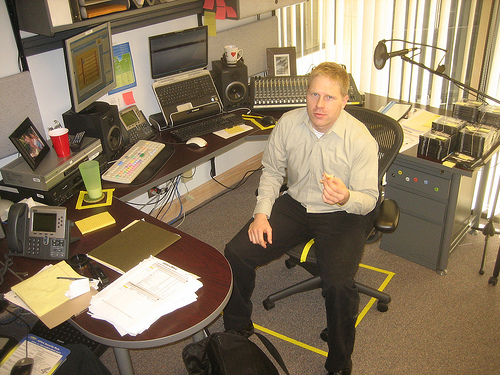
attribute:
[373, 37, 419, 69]
microphone — black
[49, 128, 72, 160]
cup — red, plastic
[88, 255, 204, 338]
papers — white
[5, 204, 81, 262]
telephone — gray, silver, black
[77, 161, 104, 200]
cup — light green, green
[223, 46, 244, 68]
mug — white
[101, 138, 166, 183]
keyboard — white, black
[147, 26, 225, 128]
laptop — gray, black, open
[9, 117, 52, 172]
frame — black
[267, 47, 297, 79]
frame — brown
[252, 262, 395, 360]
lines — yellow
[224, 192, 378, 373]
pants — black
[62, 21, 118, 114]
monitor — on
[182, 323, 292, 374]
case — black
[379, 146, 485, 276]
cabinet — gray, black